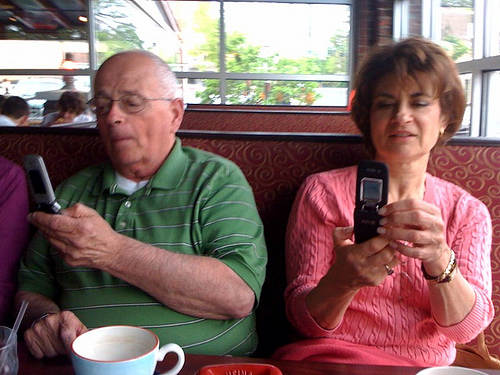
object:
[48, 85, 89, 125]
diner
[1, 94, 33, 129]
diner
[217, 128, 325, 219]
booth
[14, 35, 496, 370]
couple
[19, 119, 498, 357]
restaurant booth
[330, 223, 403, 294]
hand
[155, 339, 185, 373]
handle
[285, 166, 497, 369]
sweater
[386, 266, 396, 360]
design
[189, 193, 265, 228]
stripes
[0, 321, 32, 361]
rim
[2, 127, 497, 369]
bench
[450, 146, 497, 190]
design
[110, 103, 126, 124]
nose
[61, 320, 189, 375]
cup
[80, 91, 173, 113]
glasses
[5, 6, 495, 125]
window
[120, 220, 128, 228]
buttons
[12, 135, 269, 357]
shirt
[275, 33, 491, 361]
lady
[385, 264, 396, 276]
jewelry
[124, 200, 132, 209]
buttons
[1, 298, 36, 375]
glass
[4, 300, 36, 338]
straw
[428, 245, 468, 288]
wrist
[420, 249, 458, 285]
bracelet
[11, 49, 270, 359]
man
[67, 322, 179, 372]
mug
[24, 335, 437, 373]
table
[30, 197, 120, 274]
hand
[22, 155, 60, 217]
phone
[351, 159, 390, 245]
phone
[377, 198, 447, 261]
hand